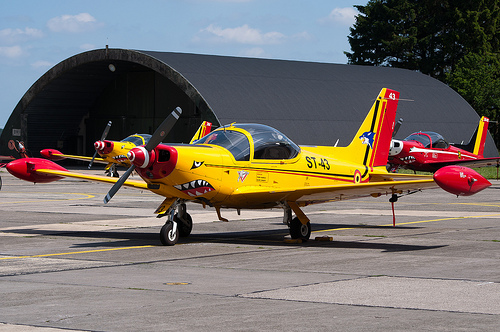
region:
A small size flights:
[18, 14, 491, 318]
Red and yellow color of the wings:
[281, 154, 493, 209]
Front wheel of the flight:
[153, 213, 206, 268]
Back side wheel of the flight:
[285, 215, 324, 244]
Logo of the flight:
[354, 125, 383, 152]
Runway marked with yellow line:
[20, 210, 141, 285]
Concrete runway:
[86, 254, 353, 316]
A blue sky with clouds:
[21, 6, 248, 38]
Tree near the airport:
[364, 3, 496, 59]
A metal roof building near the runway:
[41, 49, 428, 84]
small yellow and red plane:
[153, 138, 396, 234]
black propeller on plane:
[116, 125, 177, 206]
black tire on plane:
[289, 216, 320, 246]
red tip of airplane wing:
[435, 160, 498, 212]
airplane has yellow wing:
[257, 180, 398, 189]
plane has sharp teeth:
[178, 162, 220, 219]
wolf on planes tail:
[356, 125, 406, 174]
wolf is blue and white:
[353, 128, 384, 158]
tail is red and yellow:
[357, 113, 393, 173]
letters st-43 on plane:
[296, 153, 338, 180]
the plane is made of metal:
[132, 87, 408, 211]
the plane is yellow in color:
[143, 80, 400, 214]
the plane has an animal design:
[156, 145, 223, 199]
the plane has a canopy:
[212, 119, 298, 164]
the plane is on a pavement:
[14, 71, 429, 245]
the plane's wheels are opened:
[156, 197, 322, 253]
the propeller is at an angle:
[95, 98, 187, 214]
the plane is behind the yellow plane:
[385, 118, 495, 172]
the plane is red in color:
[385, 113, 487, 173]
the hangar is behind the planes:
[5, 39, 485, 181]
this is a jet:
[118, 133, 445, 197]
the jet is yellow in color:
[207, 167, 268, 196]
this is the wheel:
[155, 221, 192, 249]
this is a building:
[113, 42, 306, 108]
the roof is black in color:
[227, 62, 314, 94]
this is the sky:
[122, 7, 284, 42]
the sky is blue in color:
[127, 6, 174, 41]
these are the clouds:
[214, 22, 262, 43]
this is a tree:
[363, 12, 422, 54]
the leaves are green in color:
[376, 16, 406, 53]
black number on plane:
[293, 151, 333, 174]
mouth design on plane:
[169, 180, 219, 200]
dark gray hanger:
[2, 41, 497, 173]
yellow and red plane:
[10, 82, 490, 242]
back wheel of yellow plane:
[281, 212, 311, 242]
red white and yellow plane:
[375, 110, 495, 165]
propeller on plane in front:
[100, 102, 190, 203]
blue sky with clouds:
[0, 1, 345, 37]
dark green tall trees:
[345, 0, 495, 65]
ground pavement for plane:
[10, 246, 496, 322]